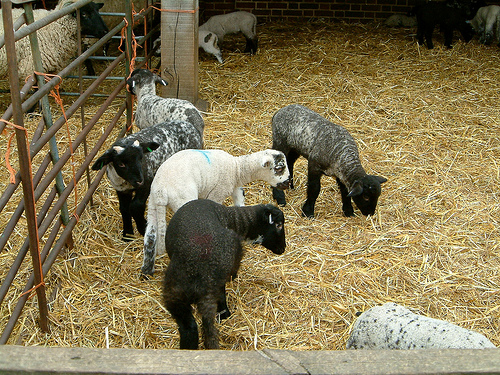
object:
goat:
[138, 148, 290, 282]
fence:
[0, 1, 161, 344]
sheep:
[90, 120, 205, 243]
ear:
[141, 141, 161, 154]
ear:
[92, 151, 113, 171]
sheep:
[123, 68, 206, 150]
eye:
[276, 224, 282, 228]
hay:
[399, 142, 494, 349]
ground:
[0, 27, 499, 351]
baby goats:
[198, 10, 259, 56]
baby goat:
[415, 5, 475, 50]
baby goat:
[466, 4, 499, 40]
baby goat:
[124, 70, 207, 142]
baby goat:
[269, 104, 387, 218]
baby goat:
[342, 300, 499, 349]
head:
[346, 175, 388, 217]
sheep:
[0, 1, 111, 120]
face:
[79, 8, 110, 39]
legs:
[272, 145, 287, 208]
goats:
[160, 197, 287, 348]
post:
[159, 0, 200, 108]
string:
[116, 6, 144, 133]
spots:
[359, 319, 434, 348]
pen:
[3, 25, 499, 343]